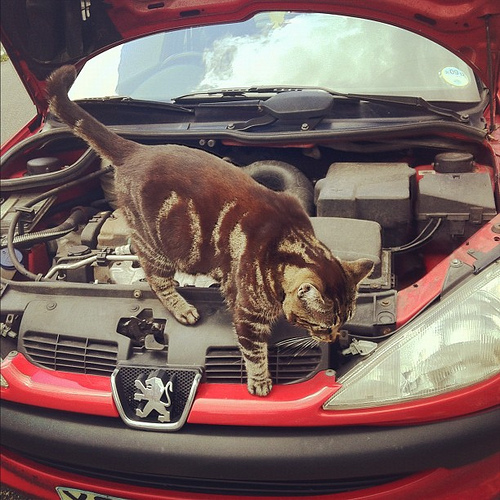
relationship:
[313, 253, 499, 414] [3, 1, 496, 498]
headlight on car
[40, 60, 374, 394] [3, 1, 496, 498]
cat on a car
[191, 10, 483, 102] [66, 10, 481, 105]
reflection of clouded sky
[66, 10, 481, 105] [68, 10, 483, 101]
clouded sky on windshield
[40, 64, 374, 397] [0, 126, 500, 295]
cat in engine compartment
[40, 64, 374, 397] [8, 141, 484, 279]
cat standing on engine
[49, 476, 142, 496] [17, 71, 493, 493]
license plate on car